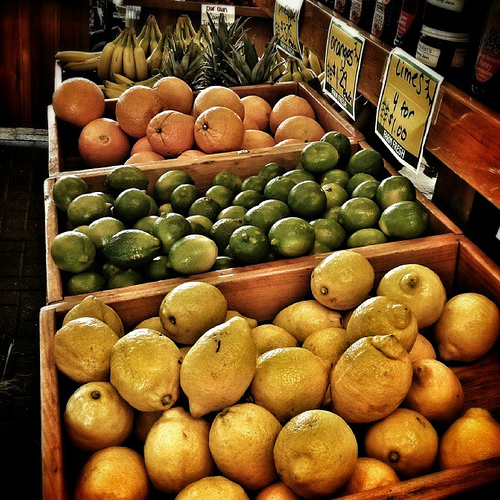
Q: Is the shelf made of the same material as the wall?
A: Yes, both the shelf and the wall are made of wood.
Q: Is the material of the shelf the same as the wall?
A: Yes, both the shelf and the wall are made of wood.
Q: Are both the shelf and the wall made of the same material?
A: Yes, both the shelf and the wall are made of wood.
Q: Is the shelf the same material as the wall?
A: Yes, both the shelf and the wall are made of wood.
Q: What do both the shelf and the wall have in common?
A: The material, both the shelf and the wall are wooden.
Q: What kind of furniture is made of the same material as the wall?
A: The shelf is made of the same material as the wall.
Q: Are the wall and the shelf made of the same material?
A: Yes, both the wall and the shelf are made of wood.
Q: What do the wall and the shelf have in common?
A: The material, both the wall and the shelf are wooden.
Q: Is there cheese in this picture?
A: No, there is no cheese.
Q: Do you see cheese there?
A: No, there is no cheese.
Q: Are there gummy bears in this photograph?
A: No, there are no gummy bears.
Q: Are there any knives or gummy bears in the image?
A: No, there are no gummy bears or knives.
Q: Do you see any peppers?
A: No, there are no peppers.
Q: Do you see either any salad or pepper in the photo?
A: No, there are no peppers or salad.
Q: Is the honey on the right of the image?
A: Yes, the honey is on the right of the image.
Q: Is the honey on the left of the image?
A: No, the honey is on the right of the image.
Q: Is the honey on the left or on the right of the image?
A: The honey is on the right of the image.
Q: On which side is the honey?
A: The honey is on the right of the image.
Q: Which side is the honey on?
A: The honey is on the right of the image.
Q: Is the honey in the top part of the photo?
A: Yes, the honey is in the top of the image.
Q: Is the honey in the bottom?
A: No, the honey is in the top of the image.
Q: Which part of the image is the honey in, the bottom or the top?
A: The honey is in the top of the image.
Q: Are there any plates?
A: No, there are no plates.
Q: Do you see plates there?
A: No, there are no plates.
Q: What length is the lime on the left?
A: The lime is long.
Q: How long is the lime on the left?
A: The lime is long.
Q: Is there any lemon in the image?
A: Yes, there are lemons.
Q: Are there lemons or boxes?
A: Yes, there are lemons.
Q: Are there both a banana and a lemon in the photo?
A: Yes, there are both a lemon and a banana.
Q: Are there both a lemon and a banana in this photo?
A: Yes, there are both a lemon and a banana.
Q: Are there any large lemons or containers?
A: Yes, there are large lemons.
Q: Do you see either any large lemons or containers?
A: Yes, there are large lemons.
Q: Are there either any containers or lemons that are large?
A: Yes, the lemons are large.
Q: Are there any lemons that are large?
A: Yes, there are large lemons.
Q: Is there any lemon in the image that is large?
A: Yes, there are lemons that are large.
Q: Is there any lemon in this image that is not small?
A: Yes, there are large lemons.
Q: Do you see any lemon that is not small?
A: Yes, there are large lemons.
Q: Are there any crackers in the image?
A: No, there are no crackers.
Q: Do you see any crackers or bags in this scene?
A: No, there are no crackers or bags.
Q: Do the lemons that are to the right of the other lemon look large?
A: Yes, the lemons are large.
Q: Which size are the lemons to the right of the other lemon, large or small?
A: The lemons are large.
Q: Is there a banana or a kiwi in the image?
A: Yes, there are bananas.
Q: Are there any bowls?
A: No, there are no bowls.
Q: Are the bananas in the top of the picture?
A: Yes, the bananas are in the top of the image.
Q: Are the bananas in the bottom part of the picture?
A: No, the bananas are in the top of the image.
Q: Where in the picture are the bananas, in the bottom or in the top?
A: The bananas are in the top of the image.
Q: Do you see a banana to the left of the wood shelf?
A: Yes, there are bananas to the left of the shelf.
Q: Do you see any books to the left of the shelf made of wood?
A: No, there are bananas to the left of the shelf.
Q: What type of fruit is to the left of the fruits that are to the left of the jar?
A: The fruits are bananas.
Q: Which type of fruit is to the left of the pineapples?
A: The fruits are bananas.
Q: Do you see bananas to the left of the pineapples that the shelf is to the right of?
A: Yes, there are bananas to the left of the pineapples.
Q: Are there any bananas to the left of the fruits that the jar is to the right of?
A: Yes, there are bananas to the left of the pineapples.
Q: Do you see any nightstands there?
A: No, there are no nightstands.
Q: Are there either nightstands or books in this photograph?
A: No, there are no nightstands or books.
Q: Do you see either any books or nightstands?
A: No, there are no nightstands or books.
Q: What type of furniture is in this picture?
A: The furniture is a shelf.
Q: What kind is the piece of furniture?
A: The piece of furniture is a shelf.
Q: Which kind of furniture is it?
A: The piece of furniture is a shelf.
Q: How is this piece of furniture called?
A: That is a shelf.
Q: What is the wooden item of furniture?
A: The piece of furniture is a shelf.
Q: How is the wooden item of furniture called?
A: The piece of furniture is a shelf.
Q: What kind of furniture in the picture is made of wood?
A: The furniture is a shelf.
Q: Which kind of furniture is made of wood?
A: The furniture is a shelf.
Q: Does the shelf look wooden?
A: Yes, the shelf is wooden.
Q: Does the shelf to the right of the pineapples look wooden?
A: Yes, the shelf is wooden.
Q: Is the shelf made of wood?
A: Yes, the shelf is made of wood.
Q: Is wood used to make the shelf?
A: Yes, the shelf is made of wood.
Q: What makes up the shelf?
A: The shelf is made of wood.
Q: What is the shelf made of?
A: The shelf is made of wood.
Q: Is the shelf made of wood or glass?
A: The shelf is made of wood.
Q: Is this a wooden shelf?
A: Yes, this is a wooden shelf.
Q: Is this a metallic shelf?
A: No, this is a wooden shelf.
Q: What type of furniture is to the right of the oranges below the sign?
A: The piece of furniture is a shelf.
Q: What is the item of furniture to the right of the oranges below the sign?
A: The piece of furniture is a shelf.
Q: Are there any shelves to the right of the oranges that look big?
A: Yes, there is a shelf to the right of the oranges.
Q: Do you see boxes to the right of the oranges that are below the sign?
A: No, there is a shelf to the right of the oranges.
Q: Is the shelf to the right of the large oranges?
A: Yes, the shelf is to the right of the oranges.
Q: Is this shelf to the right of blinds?
A: No, the shelf is to the right of the oranges.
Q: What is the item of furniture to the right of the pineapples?
A: The piece of furniture is a shelf.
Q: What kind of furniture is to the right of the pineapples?
A: The piece of furniture is a shelf.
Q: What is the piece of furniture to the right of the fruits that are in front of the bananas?
A: The piece of furniture is a shelf.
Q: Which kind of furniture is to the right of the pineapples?
A: The piece of furniture is a shelf.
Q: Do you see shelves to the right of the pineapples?
A: Yes, there is a shelf to the right of the pineapples.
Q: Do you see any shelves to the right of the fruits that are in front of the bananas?
A: Yes, there is a shelf to the right of the pineapples.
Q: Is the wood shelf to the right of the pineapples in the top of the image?
A: Yes, the shelf is to the right of the pineapples.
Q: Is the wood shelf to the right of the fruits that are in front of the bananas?
A: Yes, the shelf is to the right of the pineapples.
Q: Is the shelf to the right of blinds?
A: No, the shelf is to the right of the pineapples.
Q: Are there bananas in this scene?
A: Yes, there are bananas.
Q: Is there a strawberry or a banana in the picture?
A: Yes, there are bananas.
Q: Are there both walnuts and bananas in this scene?
A: No, there are bananas but no walnuts.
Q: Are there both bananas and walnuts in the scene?
A: No, there are bananas but no walnuts.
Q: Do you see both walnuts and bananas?
A: No, there are bananas but no walnuts.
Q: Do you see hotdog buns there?
A: No, there are no hotdog buns.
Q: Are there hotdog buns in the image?
A: No, there are no hotdog buns.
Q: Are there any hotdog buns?
A: No, there are no hotdog buns.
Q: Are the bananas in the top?
A: Yes, the bananas are in the top of the image.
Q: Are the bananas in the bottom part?
A: No, the bananas are in the top of the image.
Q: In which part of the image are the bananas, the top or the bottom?
A: The bananas are in the top of the image.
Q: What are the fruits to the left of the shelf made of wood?
A: The fruits are bananas.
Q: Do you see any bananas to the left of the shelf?
A: Yes, there are bananas to the left of the shelf.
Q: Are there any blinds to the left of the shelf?
A: No, there are bananas to the left of the shelf.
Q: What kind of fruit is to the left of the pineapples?
A: The fruits are bananas.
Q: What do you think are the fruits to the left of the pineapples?
A: The fruits are bananas.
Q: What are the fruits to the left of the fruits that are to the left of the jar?
A: The fruits are bananas.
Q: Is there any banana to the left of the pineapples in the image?
A: Yes, there are bananas to the left of the pineapples.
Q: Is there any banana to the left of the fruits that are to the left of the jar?
A: Yes, there are bananas to the left of the pineapples.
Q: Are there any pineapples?
A: Yes, there are pineapples.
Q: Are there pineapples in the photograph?
A: Yes, there are pineapples.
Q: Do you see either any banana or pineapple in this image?
A: Yes, there are pineapples.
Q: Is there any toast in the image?
A: No, there are no toasts.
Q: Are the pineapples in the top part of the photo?
A: Yes, the pineapples are in the top of the image.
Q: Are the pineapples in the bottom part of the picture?
A: No, the pineapples are in the top of the image.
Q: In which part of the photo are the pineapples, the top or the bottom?
A: The pineapples are in the top of the image.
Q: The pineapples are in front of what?
A: The pineapples are in front of the bananas.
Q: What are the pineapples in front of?
A: The pineapples are in front of the bananas.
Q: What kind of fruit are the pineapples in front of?
A: The pineapples are in front of the bananas.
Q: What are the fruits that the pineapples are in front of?
A: The fruits are bananas.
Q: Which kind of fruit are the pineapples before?
A: The pineapples are in front of the bananas.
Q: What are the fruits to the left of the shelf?
A: The fruits are pineapples.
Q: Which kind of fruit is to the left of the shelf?
A: The fruits are pineapples.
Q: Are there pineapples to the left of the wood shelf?
A: Yes, there are pineapples to the left of the shelf.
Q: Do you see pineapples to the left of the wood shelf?
A: Yes, there are pineapples to the left of the shelf.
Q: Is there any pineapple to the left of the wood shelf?
A: Yes, there are pineapples to the left of the shelf.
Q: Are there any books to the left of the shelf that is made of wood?
A: No, there are pineapples to the left of the shelf.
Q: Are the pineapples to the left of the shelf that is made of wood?
A: Yes, the pineapples are to the left of the shelf.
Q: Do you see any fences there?
A: No, there are no fences.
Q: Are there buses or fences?
A: No, there are no fences or buses.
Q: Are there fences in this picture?
A: No, there are no fences.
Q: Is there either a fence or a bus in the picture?
A: No, there are no fences or buses.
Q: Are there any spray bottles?
A: No, there are no spray bottles.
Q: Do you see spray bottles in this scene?
A: No, there are no spray bottles.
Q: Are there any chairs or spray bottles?
A: No, there are no spray bottles or chairs.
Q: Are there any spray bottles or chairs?
A: No, there are no spray bottles or chairs.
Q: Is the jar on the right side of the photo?
A: Yes, the jar is on the right of the image.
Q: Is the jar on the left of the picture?
A: No, the jar is on the right of the image.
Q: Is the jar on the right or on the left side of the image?
A: The jar is on the right of the image.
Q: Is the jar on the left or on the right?
A: The jar is on the right of the image.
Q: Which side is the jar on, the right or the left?
A: The jar is on the right of the image.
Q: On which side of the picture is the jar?
A: The jar is on the right of the image.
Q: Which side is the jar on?
A: The jar is on the right of the image.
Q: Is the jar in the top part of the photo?
A: Yes, the jar is in the top of the image.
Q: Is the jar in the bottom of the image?
A: No, the jar is in the top of the image.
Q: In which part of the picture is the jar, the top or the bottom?
A: The jar is in the top of the image.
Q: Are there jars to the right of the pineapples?
A: Yes, there is a jar to the right of the pineapples.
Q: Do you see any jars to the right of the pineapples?
A: Yes, there is a jar to the right of the pineapples.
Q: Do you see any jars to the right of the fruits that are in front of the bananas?
A: Yes, there is a jar to the right of the pineapples.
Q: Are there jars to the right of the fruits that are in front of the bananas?
A: Yes, there is a jar to the right of the pineapples.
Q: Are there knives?
A: No, there are no knives.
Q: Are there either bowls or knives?
A: No, there are no knives or bowls.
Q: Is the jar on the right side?
A: Yes, the jar is on the right of the image.